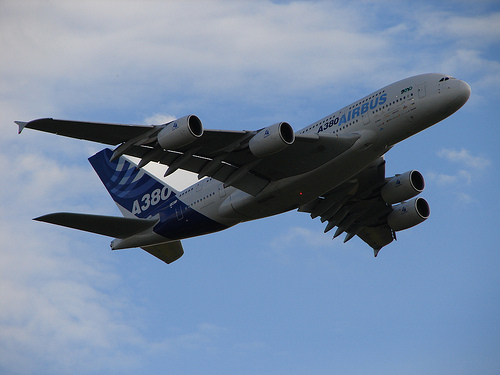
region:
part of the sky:
[448, 279, 463, 299]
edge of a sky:
[298, 334, 308, 346]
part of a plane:
[196, 199, 218, 218]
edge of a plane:
[253, 191, 281, 236]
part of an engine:
[216, 137, 254, 172]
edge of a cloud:
[231, 283, 251, 318]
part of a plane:
[354, 226, 366, 247]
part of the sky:
[276, 278, 298, 321]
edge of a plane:
[151, 193, 158, 200]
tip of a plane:
[295, 142, 345, 232]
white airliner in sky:
[104, 50, 386, 242]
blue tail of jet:
[84, 144, 202, 242]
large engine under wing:
[157, 103, 209, 153]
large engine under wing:
[232, 125, 300, 170]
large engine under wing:
[386, 176, 421, 206]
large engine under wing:
[400, 205, 430, 232]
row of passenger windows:
[332, 112, 374, 147]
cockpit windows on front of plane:
[424, 60, 462, 105]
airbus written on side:
[334, 99, 401, 117]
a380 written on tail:
[137, 182, 156, 223]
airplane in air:
[29, 55, 486, 265]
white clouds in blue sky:
[75, 285, 139, 338]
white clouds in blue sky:
[271, 320, 311, 342]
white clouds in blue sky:
[146, 65, 236, 98]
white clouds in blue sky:
[27, 36, 77, 74]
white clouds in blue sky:
[394, 299, 469, 353]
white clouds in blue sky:
[13, 295, 84, 336]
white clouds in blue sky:
[240, 48, 297, 93]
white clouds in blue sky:
[355, 9, 435, 64]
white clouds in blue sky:
[187, 21, 288, 89]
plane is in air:
[67, 61, 454, 273]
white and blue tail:
[58, 153, 219, 244]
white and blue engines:
[205, 115, 443, 270]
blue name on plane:
[312, 83, 392, 140]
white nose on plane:
[388, 83, 468, 115]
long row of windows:
[318, 78, 435, 142]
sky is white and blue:
[152, 21, 290, 112]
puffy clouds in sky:
[0, 14, 311, 106]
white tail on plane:
[77, 204, 162, 271]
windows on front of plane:
[425, 74, 457, 98]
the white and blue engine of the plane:
[155, 115, 198, 145]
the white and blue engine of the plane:
[249, 116, 292, 155]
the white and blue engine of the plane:
[384, 168, 423, 204]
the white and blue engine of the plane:
[392, 197, 428, 229]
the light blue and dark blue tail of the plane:
[88, 144, 174, 214]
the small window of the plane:
[437, 75, 444, 82]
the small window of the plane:
[441, 73, 451, 83]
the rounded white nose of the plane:
[430, 71, 469, 108]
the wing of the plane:
[18, 114, 306, 187]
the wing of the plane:
[317, 156, 396, 251]